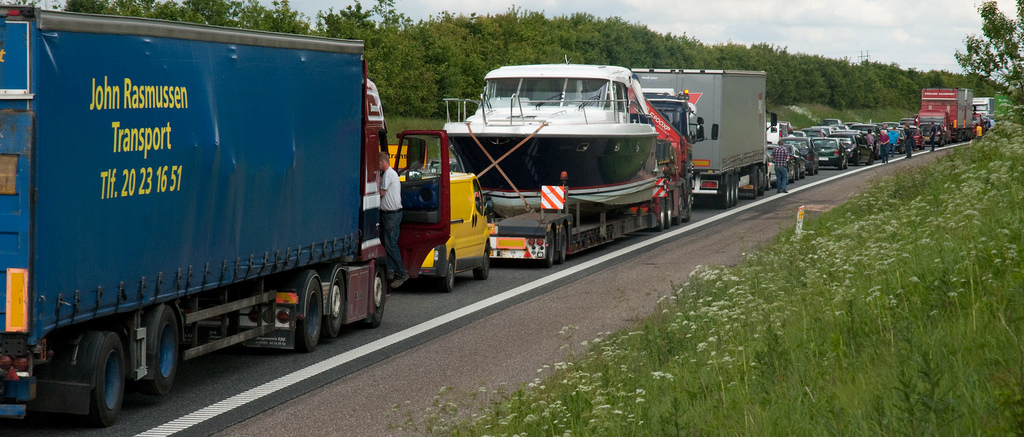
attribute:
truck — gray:
[629, 70, 784, 191]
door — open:
[369, 123, 459, 269]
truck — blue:
[21, 14, 464, 318]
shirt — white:
[376, 169, 409, 205]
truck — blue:
[2, 1, 467, 368]